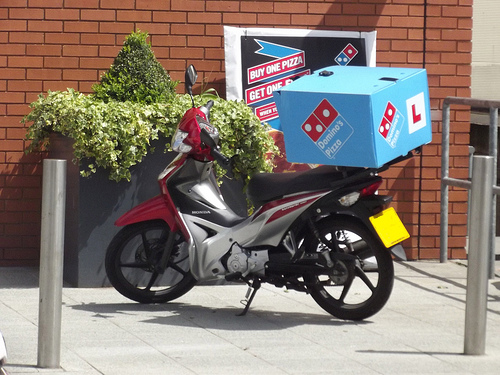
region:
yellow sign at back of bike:
[361, 203, 437, 250]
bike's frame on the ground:
[221, 274, 268, 320]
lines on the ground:
[86, 324, 188, 367]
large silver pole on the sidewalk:
[17, 302, 75, 355]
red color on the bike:
[110, 181, 184, 223]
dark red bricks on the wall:
[414, 187, 436, 216]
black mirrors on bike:
[172, 64, 229, 104]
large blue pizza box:
[250, 49, 440, 179]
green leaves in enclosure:
[8, 85, 274, 165]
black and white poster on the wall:
[184, 22, 405, 77]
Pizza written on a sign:
[279, 48, 308, 72]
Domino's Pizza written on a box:
[292, 96, 360, 163]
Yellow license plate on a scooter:
[359, 201, 413, 255]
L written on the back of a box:
[398, 88, 433, 138]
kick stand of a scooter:
[226, 273, 273, 325]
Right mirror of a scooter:
[177, 59, 208, 95]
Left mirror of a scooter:
[191, 126, 221, 156]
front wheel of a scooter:
[100, 204, 208, 312]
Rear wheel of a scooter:
[295, 208, 397, 325]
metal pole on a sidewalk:
[18, 151, 81, 373]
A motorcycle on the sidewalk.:
[132, 118, 403, 313]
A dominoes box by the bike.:
[273, 50, 448, 176]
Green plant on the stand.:
[49, 64, 266, 161]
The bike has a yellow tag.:
[366, 209, 422, 246]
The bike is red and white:
[134, 108, 206, 219]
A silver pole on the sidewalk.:
[22, 139, 85, 360]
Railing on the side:
[440, 59, 495, 252]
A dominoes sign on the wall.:
[215, 4, 410, 131]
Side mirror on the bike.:
[171, 63, 200, 108]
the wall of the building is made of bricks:
[0, 0, 470, 259]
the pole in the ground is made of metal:
[32, 159, 68, 371]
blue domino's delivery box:
[280, 45, 425, 156]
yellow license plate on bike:
[372, 185, 414, 270]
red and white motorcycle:
[115, 101, 400, 331]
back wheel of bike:
[290, 197, 392, 329]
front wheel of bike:
[112, 195, 222, 320]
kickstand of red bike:
[220, 260, 290, 325]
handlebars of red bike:
[180, 92, 237, 177]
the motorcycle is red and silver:
[105, 63, 409, 320]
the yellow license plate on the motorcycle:
[106, 62, 409, 320]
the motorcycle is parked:
[106, 64, 410, 320]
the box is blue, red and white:
[275, 60, 432, 171]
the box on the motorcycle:
[105, 58, 432, 321]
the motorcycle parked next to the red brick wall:
[1, 0, 475, 321]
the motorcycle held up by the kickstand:
[104, 63, 409, 317]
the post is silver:
[36, 158, 65, 368]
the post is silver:
[463, 155, 495, 355]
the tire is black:
[105, 220, 197, 302]